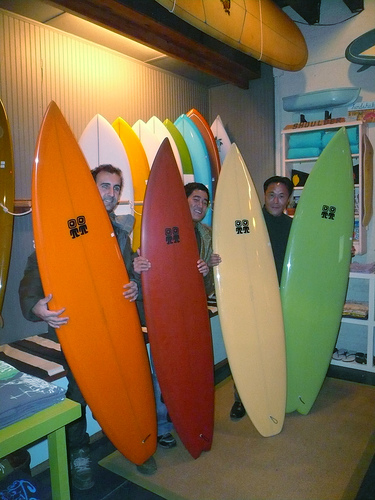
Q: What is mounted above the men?
A: A surfboard.